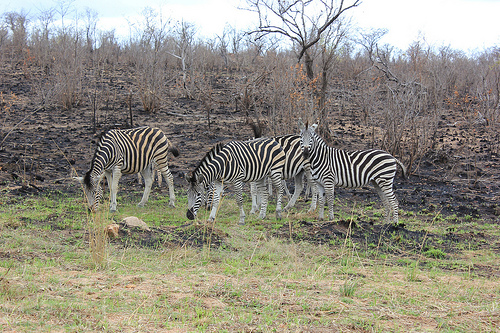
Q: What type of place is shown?
A: It is a field.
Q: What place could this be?
A: It is a field.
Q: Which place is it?
A: It is a field.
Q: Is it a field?
A: Yes, it is a field.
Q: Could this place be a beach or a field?
A: It is a field.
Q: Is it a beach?
A: No, it is a field.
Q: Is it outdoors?
A: Yes, it is outdoors.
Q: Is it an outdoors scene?
A: Yes, it is outdoors.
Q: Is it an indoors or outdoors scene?
A: It is outdoors.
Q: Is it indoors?
A: No, it is outdoors.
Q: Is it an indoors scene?
A: No, it is outdoors.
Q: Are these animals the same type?
A: Yes, all the animals are zebras.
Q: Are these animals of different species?
A: No, all the animals are zebras.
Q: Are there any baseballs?
A: No, there are no baseballs.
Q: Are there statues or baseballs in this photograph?
A: No, there are no baseballs or statues.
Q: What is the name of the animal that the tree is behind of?
A: The animal is a zebra.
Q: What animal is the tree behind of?
A: The tree is behind the zebra.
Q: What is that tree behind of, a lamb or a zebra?
A: The tree is behind a zebra.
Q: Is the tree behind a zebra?
A: Yes, the tree is behind a zebra.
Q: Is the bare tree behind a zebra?
A: Yes, the tree is behind a zebra.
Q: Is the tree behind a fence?
A: No, the tree is behind a zebra.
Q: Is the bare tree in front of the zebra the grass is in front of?
A: No, the tree is behind the zebra.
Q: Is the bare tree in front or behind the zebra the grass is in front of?
A: The tree is behind the zebra.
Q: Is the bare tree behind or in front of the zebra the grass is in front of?
A: The tree is behind the zebra.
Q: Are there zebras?
A: Yes, there is a zebra.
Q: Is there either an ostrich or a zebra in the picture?
A: Yes, there is a zebra.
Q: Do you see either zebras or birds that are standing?
A: Yes, the zebra is standing.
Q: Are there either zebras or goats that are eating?
A: Yes, the zebra is eating.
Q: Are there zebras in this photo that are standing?
A: Yes, there is a zebra that is standing.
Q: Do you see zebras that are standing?
A: Yes, there is a zebra that is standing.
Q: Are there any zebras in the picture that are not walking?
A: Yes, there is a zebra that is standing.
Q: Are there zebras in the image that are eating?
A: Yes, there is a zebra that is eating.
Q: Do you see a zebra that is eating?
A: Yes, there is a zebra that is eating.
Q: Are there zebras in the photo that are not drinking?
A: Yes, there is a zebra that is eating.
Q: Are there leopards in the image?
A: No, there are no leopards.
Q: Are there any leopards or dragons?
A: No, there are no leopards or dragons.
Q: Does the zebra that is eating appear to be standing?
A: Yes, the zebra is standing.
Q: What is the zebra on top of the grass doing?
A: The zebra is standing.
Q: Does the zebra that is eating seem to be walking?
A: No, the zebra is standing.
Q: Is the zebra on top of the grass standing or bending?
A: The zebra is standing.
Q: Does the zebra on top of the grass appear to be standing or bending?
A: The zebra is standing.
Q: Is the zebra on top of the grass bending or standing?
A: The zebra is standing.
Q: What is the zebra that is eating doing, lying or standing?
A: The zebra is standing.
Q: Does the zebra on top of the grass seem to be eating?
A: Yes, the zebra is eating.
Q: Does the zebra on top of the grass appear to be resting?
A: No, the zebra is eating.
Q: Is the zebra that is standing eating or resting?
A: The zebra is eating.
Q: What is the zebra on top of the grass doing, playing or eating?
A: The zebra is eating.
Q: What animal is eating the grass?
A: The zebra is eating the grass.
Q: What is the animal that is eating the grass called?
A: The animal is a zebra.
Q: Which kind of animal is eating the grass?
A: The animal is a zebra.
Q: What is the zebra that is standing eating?
A: The zebra is eating grass.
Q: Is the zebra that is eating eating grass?
A: Yes, the zebra is eating grass.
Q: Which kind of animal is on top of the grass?
A: The animal is a zebra.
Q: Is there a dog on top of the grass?
A: No, there is a zebra on top of the grass.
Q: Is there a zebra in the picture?
A: Yes, there is a zebra.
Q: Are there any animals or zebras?
A: Yes, there is a zebra.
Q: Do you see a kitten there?
A: No, there are no kittens.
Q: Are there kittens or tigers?
A: No, there are no kittens or tigers.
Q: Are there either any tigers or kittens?
A: No, there are no kittens or tigers.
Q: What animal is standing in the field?
A: The animal is a zebra.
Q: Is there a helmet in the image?
A: No, there are no helmets.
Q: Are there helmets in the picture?
A: No, there are no helmets.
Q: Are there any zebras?
A: Yes, there is a zebra.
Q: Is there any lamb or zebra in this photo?
A: Yes, there is a zebra.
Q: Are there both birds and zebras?
A: No, there is a zebra but no birds.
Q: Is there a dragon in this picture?
A: No, there are no dragons.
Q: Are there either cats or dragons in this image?
A: No, there are no dragons or cats.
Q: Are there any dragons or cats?
A: No, there are no dragons or cats.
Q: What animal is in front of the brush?
A: The animal is a zebra.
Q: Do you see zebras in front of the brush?
A: Yes, there is a zebra in front of the brush.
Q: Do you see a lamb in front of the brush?
A: No, there is a zebra in front of the brush.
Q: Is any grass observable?
A: Yes, there is grass.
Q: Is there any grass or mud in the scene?
A: Yes, there is grass.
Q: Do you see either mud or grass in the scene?
A: Yes, there is grass.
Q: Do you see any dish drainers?
A: No, there are no dish drainers.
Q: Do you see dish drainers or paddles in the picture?
A: No, there are no dish drainers or paddles.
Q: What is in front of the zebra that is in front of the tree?
A: The grass is in front of the zebra.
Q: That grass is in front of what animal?
A: The grass is in front of the zebra.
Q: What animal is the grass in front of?
A: The grass is in front of the zebra.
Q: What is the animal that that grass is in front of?
A: The animal is a zebra.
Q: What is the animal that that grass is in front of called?
A: The animal is a zebra.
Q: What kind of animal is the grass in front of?
A: The grass is in front of the zebra.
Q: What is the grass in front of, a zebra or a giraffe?
A: The grass is in front of a zebra.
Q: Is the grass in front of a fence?
A: No, the grass is in front of the zebra.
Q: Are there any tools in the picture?
A: No, there are no tools.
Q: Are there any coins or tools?
A: No, there are no tools or coins.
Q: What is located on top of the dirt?
A: The rock is on top of the dirt.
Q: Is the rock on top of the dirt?
A: Yes, the rock is on top of the dirt.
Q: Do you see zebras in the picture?
A: Yes, there is a zebra.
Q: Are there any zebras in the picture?
A: Yes, there is a zebra.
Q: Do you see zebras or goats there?
A: Yes, there is a zebra.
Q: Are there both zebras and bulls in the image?
A: No, there is a zebra but no bulls.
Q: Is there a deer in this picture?
A: No, there is no deer.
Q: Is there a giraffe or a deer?
A: No, there are no deer or giraffes.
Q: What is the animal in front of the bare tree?
A: The animal is a zebra.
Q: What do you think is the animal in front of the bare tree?
A: The animal is a zebra.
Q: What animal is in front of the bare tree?
A: The animal is a zebra.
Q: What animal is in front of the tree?
A: The animal is a zebra.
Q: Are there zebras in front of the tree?
A: Yes, there is a zebra in front of the tree.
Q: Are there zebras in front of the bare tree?
A: Yes, there is a zebra in front of the tree.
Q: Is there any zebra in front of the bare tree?
A: Yes, there is a zebra in front of the tree.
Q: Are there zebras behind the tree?
A: No, the zebra is in front of the tree.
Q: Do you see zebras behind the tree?
A: No, the zebra is in front of the tree.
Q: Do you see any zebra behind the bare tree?
A: No, the zebra is in front of the tree.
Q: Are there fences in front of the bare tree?
A: No, there is a zebra in front of the tree.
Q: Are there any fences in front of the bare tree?
A: No, there is a zebra in front of the tree.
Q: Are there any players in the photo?
A: No, there are no players.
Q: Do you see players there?
A: No, there are no players.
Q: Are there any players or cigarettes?
A: No, there are no players or cigarettes.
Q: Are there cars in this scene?
A: No, there are no cars.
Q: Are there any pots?
A: No, there are no pots.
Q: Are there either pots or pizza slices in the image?
A: No, there are no pots or pizza slices.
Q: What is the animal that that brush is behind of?
A: The animal is a zebra.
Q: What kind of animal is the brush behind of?
A: The brush is behind the zebra.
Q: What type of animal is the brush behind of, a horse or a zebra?
A: The brush is behind a zebra.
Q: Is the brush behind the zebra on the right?
A: Yes, the brush is behind the zebra.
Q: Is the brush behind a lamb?
A: No, the brush is behind the zebra.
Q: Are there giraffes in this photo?
A: No, there are no giraffes.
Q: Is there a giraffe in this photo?
A: No, there are no giraffes.